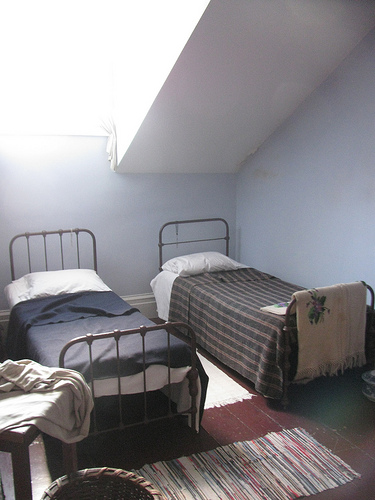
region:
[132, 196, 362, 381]
a bed in the room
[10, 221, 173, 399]
another bed in room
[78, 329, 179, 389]
a iron stand of bed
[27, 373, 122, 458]
a cloth in bed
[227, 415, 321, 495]
a carpet in floor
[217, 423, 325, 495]
a carpet in ground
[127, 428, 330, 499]
A rug in on the floor.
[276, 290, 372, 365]
A blanket on the back of the bed.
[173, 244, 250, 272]
A white pillow on the bed.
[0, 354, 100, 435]
Clothes on the table.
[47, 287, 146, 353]
Blue blanket on the bed.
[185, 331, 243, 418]
White rug on the floor.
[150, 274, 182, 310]
The sheets are white.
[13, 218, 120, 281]
The headborad is iron rod.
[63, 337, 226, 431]
The footboard is iron rods.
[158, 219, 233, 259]
black metal frame of bed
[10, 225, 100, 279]
black metal frame of bed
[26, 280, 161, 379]
blue sheets on bed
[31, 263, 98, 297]
white pillow on bed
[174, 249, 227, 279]
white pillow on bed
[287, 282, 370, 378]
white blanket on end of bed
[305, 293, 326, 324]
image on white blanket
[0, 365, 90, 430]
white blanket on stool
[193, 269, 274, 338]
black and white bed spread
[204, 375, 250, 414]
white rug on the floor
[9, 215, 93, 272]
top part of bed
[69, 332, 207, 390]
back part of bed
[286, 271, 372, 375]
a towel in the bed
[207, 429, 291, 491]
a carpet in the floor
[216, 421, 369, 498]
a carpet in the ground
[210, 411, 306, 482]
a carpet in the ground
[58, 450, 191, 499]
a part of dust bin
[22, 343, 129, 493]
a cloth on the side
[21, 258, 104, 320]
a pillow on bed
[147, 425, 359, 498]
mat on the floor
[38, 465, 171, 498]
basket by the mat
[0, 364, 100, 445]
blanket sitting on table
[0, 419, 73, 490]
legs of desk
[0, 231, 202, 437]
bed with metal frame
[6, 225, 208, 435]
bed with white sheets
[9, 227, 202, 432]
bed with black blanket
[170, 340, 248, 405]
white rug between two beds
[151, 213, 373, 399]
bed with blanket at edge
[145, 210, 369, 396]
bed with white pillow